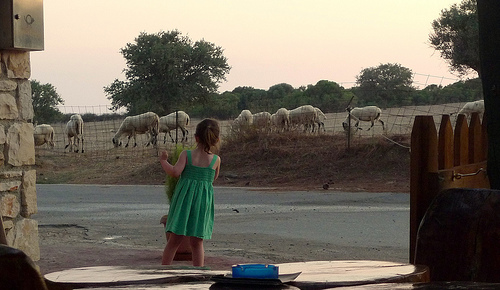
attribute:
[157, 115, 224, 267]
girl — little, young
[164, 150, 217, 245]
dress — green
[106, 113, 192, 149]
animals — white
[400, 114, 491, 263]
gate — wood, brown, wooden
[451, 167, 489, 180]
handle — silver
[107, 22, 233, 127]
tree — large, dark green, green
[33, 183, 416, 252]
road — paved, street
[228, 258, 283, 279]
ashtray — blue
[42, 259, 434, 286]
table — round, brown, wooden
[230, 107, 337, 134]
sheep — white, grazing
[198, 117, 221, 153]
hair — brown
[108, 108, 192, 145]
sheep — white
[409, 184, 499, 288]
chair — dirty looking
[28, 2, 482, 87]
sky — clear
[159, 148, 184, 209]
plant — green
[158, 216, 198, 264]
flower pot — pink